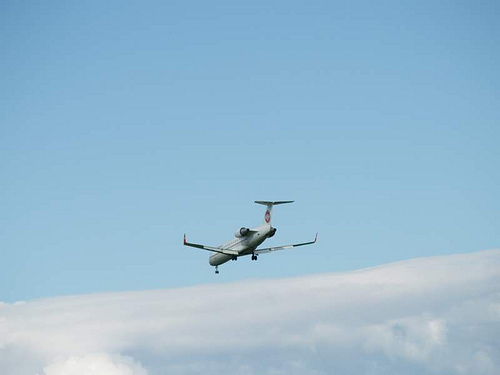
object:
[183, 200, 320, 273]
plane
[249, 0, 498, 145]
air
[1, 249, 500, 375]
cloud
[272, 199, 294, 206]
tail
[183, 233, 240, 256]
wing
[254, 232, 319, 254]
wing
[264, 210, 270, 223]
circle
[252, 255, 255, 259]
wheel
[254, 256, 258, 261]
wheel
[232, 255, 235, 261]
wheel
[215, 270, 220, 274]
gear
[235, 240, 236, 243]
windows